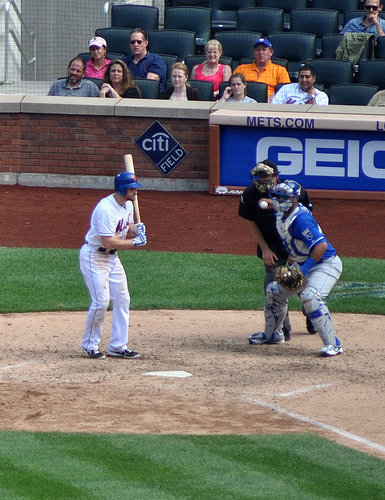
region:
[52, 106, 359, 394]
catcher throwing back a ball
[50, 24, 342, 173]
people watching a baseball game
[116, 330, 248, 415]
a white home plate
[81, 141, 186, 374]
a baseball player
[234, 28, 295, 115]
man in blue hat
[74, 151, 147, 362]
person is batting in game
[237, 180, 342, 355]
catcher is holding the ball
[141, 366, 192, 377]
homeplate base is white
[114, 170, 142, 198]
batters helmet is blue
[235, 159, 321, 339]
umpire standing behind catcher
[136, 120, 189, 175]
blue citi field sign on wall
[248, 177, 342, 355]
blue and white catcher uniform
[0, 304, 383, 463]
light brown dirt on field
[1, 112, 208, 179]
red brick behind batter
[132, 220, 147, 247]
blue and white gloves on person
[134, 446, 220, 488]
Green playing field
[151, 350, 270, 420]
A dirt track in the photo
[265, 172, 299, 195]
Helmet in the photo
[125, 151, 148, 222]
A baseball bat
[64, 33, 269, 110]
People watching the game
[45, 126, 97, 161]
Bricks on the wall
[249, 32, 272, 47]
A blue cap in the photo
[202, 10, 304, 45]
Seats at the stadium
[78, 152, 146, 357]
man carrying a wooden bat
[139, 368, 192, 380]
home plate on a baseball diamond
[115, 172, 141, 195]
a ball player's helmet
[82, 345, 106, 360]
a ball player's right foot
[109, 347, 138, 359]
a ball player's left foot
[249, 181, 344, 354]
a baseball catcher throwing a ball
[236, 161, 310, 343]
umpire in a ball game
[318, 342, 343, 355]
a catcher's left foot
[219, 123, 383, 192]
a blue and white Geico sign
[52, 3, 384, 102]
spectators at a ball game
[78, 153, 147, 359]
Baseball player holding a bat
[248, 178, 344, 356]
Catcher holding a baseball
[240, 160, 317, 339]
Umpire standing behind the catcher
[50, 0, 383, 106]
People watching from the stands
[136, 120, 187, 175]
Citi Field sign on the wall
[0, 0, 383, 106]
Protective netting in front of fans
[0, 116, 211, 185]
Brick wall at edge of field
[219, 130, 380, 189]
Blue advertisement with white letters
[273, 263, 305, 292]
Baseball mitt on catcher's left hand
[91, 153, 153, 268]
he plays for the Mets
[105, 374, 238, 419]
There is mud on the field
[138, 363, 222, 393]
Homebase is empty right now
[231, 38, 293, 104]
Man sitting in an orange shirt and blue cap.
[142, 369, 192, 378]
A white home base.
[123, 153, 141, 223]
A wooden baseball bat.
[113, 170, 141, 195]
Blue helmet on a batter.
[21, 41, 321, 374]
this is a basball game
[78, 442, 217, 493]
the grass is light green and mowed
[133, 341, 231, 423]
this is home plate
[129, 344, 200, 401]
home plate is white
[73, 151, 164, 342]
the man is batting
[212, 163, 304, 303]
this is the umpire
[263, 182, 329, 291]
this is the catcher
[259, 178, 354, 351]
a catcher at a baseball game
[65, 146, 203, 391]
a baseball player standing at the plate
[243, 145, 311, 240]
an umpire behind the plate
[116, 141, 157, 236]
a tan colored baseball bat